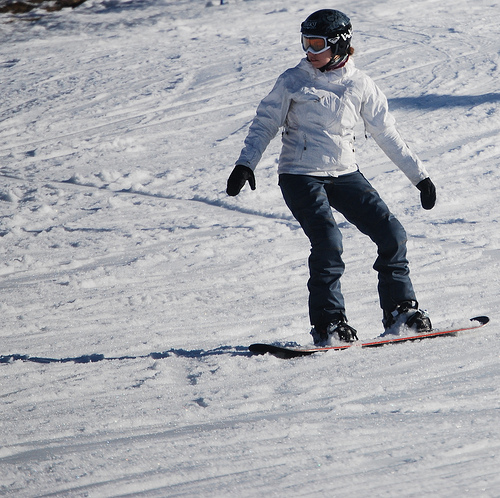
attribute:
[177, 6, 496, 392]
person — snowboarding, enjoying day, watching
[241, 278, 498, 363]
snowboard — coasting, red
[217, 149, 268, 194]
gloves — black, warm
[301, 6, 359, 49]
helmet — black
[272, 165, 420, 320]
pants — black, warm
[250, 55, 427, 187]
jacket — white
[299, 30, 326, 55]
goggles — white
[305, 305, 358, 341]
boots — black